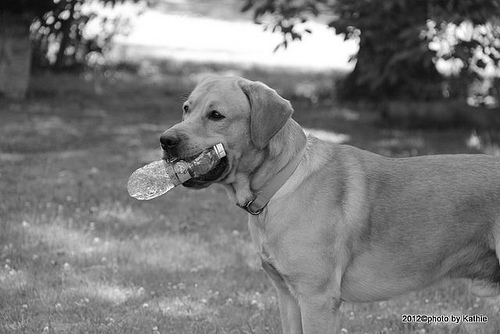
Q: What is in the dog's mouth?
A: Bottle.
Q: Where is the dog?
A: Park.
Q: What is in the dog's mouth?
A: A bottle.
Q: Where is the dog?
A: Outside on the grass.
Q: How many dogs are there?
A: 1.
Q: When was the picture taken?
A: Daytime.